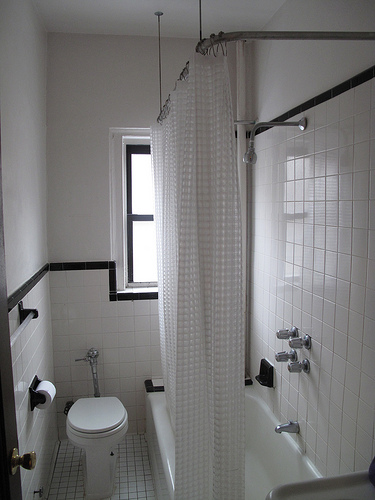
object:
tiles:
[134, 429, 147, 486]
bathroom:
[0, 1, 374, 499]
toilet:
[67, 395, 131, 496]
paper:
[36, 380, 57, 408]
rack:
[26, 374, 47, 410]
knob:
[14, 450, 37, 474]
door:
[0, 194, 26, 498]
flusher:
[76, 346, 89, 368]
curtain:
[147, 49, 250, 498]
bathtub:
[145, 381, 324, 500]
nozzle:
[272, 417, 301, 440]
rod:
[156, 4, 167, 113]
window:
[118, 129, 163, 296]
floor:
[50, 426, 154, 499]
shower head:
[243, 117, 265, 171]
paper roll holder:
[30, 375, 46, 415]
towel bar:
[18, 301, 41, 325]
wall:
[250, 78, 375, 478]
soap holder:
[254, 361, 277, 390]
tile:
[51, 313, 158, 334]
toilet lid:
[69, 398, 126, 433]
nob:
[14, 448, 48, 477]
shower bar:
[239, 111, 321, 163]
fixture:
[275, 327, 289, 340]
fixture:
[285, 335, 310, 347]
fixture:
[275, 348, 289, 365]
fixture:
[288, 359, 310, 380]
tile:
[51, 259, 112, 272]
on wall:
[1, 0, 196, 500]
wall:
[1, 5, 59, 500]